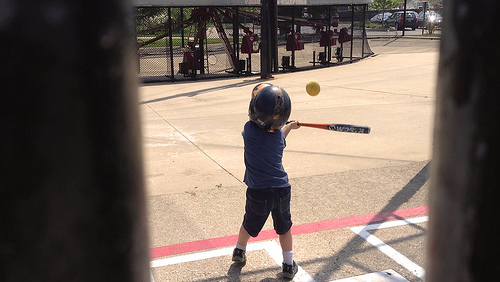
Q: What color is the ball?
A: Yellow.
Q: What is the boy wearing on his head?
A: A helmet.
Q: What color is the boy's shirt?
A: Blue.